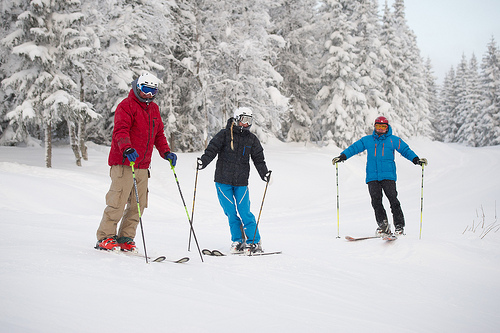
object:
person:
[328, 113, 433, 245]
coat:
[335, 128, 425, 184]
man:
[85, 65, 182, 260]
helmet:
[135, 71, 163, 91]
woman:
[188, 102, 277, 256]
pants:
[210, 177, 269, 247]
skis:
[340, 231, 386, 244]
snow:
[1, 132, 500, 330]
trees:
[455, 33, 499, 144]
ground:
[0, 156, 93, 332]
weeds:
[458, 197, 500, 242]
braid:
[228, 122, 238, 153]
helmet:
[229, 104, 258, 121]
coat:
[104, 88, 184, 172]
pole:
[125, 155, 152, 262]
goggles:
[140, 85, 161, 97]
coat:
[196, 120, 275, 187]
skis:
[88, 245, 189, 265]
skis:
[208, 248, 291, 259]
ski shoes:
[94, 234, 125, 256]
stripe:
[215, 183, 236, 209]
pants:
[361, 177, 408, 235]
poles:
[412, 151, 430, 248]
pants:
[95, 163, 155, 243]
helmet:
[375, 115, 390, 125]